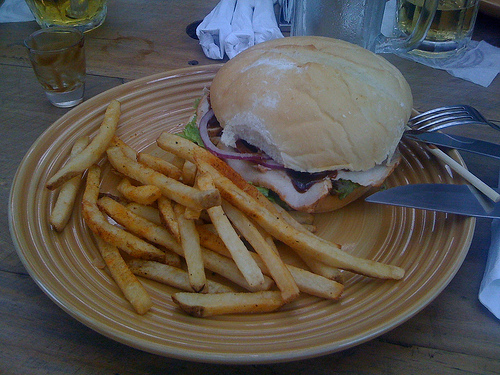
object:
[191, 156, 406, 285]
french fries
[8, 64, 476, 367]
plate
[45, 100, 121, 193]
french fry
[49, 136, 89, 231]
french fry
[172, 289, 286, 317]
french fry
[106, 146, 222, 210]
french fry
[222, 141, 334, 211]
ham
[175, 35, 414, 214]
sandwich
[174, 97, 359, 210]
lettuce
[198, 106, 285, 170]
onion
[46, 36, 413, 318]
meal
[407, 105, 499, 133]
fork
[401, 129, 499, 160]
butterknife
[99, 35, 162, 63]
stain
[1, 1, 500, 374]
table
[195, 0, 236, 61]
napkin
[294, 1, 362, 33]
water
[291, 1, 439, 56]
pitcher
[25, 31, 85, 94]
drink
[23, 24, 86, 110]
glass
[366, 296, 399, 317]
lines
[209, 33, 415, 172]
top bun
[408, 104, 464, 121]
tines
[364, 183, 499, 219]
blade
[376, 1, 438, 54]
handle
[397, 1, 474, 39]
beer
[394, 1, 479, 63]
pitcher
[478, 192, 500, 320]
napkins